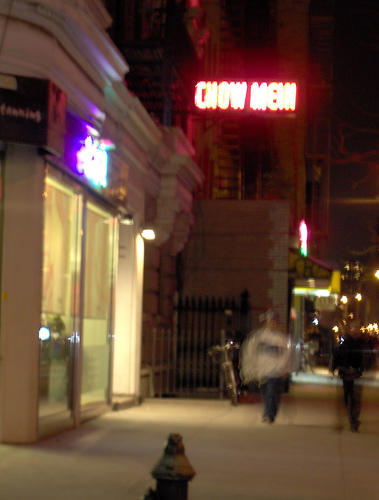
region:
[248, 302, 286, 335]
head of a person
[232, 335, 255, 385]
arm of a person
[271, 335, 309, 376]
arm of a person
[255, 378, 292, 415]
leg of a person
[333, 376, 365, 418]
leg of a person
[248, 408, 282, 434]
feet of a person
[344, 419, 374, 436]
feet of a person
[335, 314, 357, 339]
head of a person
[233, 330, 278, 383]
an arm of a person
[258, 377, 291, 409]
a leg of a person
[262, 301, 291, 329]
head of a person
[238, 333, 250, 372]
arm of a person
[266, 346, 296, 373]
arm of a person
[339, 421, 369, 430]
feet of a person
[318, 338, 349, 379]
arm of a person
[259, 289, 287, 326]
a head of a person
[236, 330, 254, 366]
an arm of a person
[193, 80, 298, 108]
two glowing words of sign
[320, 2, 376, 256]
darkness of night sign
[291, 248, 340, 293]
side of awning on building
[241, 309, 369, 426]
two people walking on sidewalk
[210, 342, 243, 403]
parked bike on sidewalk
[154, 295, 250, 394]
metal poles of fence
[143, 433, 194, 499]
top of fire hydrant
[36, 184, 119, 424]
windows of commercial business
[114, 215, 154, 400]
glowing light over doorway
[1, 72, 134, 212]
sign on front of building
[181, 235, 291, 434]
a tall metal fence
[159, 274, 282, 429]
a tall black fence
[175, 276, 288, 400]
a fence that is tall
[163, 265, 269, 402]
a fence that is black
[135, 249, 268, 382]
a tall fence that is black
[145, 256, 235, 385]
a black fence that is tall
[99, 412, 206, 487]
a fire hydrant on the sidewalk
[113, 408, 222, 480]
a hydrant on the sidewalk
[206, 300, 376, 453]
a prson on the sidewalk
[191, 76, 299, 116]
neon sign on side of building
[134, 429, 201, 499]
fire hydrant in foreground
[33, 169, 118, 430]
tall glass windows on building front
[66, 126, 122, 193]
lighted sign over doorway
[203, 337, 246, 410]
bicycle parked on sidewalk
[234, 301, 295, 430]
person in white shirt on sidewalk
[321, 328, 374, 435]
person dressed in black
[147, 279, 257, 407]
iron fence beyond bicycle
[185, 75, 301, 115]
sign that reads CHOW MEIN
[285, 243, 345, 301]
awning on side of building